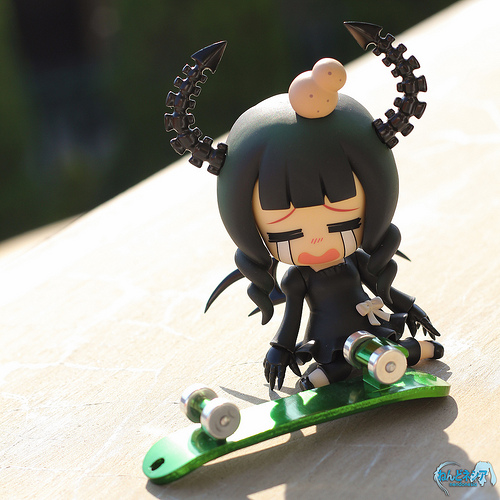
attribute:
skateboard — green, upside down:
[141, 333, 450, 478]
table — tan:
[0, 1, 499, 499]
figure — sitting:
[162, 20, 444, 390]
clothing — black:
[261, 253, 446, 390]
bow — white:
[355, 296, 392, 328]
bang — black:
[258, 145, 355, 208]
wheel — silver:
[371, 344, 406, 382]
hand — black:
[405, 302, 440, 340]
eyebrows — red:
[265, 198, 359, 226]